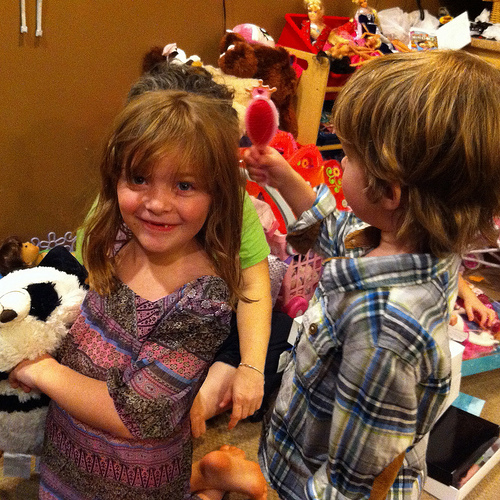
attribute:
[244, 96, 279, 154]
brush — small, pink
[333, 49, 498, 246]
hair — blond 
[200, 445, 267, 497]
feet — small, bare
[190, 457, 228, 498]
ankles — crossed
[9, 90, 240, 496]
girl — little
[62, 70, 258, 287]
hair — girl's